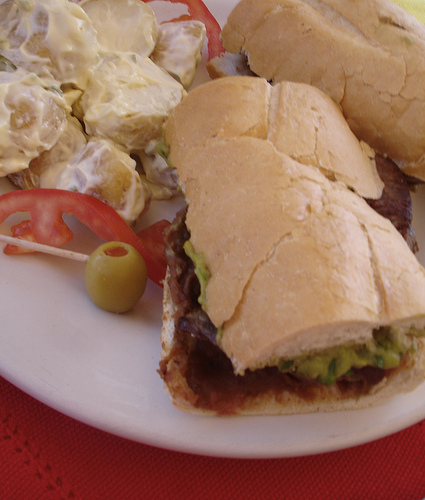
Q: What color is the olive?
A: Green.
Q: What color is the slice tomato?
A: Red.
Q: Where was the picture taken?
A: In a restaurant.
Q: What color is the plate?
A: White.